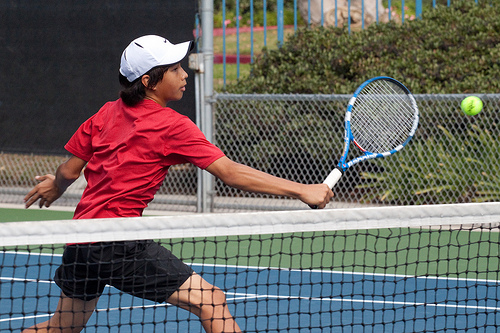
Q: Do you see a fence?
A: Yes, there is a fence.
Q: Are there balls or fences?
A: Yes, there is a fence.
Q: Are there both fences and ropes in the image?
A: No, there is a fence but no ropes.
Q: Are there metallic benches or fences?
A: Yes, there is a metal fence.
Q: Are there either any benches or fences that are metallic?
A: Yes, the fence is metallic.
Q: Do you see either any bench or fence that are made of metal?
A: Yes, the fence is made of metal.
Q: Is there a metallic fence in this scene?
A: Yes, there is a metal fence.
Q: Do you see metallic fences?
A: Yes, there is a metal fence.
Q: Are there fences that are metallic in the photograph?
A: Yes, there is a metal fence.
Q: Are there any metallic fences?
A: Yes, there is a metal fence.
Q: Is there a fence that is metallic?
A: Yes, there is a fence that is metallic.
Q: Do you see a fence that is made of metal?
A: Yes, there is a fence that is made of metal.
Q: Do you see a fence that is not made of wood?
A: Yes, there is a fence that is made of metal.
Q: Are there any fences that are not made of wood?
A: Yes, there is a fence that is made of metal.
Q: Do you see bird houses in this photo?
A: No, there are no bird houses.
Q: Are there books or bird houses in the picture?
A: No, there are no bird houses or books.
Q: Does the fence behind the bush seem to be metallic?
A: Yes, the fence is metallic.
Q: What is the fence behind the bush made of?
A: The fence is made of metal.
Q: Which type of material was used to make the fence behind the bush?
A: The fence is made of metal.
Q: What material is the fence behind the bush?
A: The fence is made of metal.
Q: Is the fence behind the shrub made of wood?
A: No, the fence is made of metal.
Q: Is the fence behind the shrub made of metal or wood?
A: The fence is made of metal.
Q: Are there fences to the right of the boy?
A: Yes, there is a fence to the right of the boy.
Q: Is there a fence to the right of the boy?
A: Yes, there is a fence to the right of the boy.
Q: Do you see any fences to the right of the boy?
A: Yes, there is a fence to the right of the boy.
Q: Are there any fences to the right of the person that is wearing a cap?
A: Yes, there is a fence to the right of the boy.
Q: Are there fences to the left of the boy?
A: No, the fence is to the right of the boy.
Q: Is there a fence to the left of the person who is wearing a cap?
A: No, the fence is to the right of the boy.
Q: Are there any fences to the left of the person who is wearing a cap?
A: No, the fence is to the right of the boy.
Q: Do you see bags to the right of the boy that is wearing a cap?
A: No, there is a fence to the right of the boy.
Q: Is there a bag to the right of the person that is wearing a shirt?
A: No, there is a fence to the right of the boy.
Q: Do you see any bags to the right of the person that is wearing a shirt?
A: No, there is a fence to the right of the boy.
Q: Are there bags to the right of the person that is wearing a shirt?
A: No, there is a fence to the right of the boy.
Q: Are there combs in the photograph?
A: No, there are no combs.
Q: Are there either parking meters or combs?
A: No, there are no combs or parking meters.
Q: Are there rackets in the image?
A: Yes, there is a racket.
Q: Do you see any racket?
A: Yes, there is a racket.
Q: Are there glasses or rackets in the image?
A: Yes, there is a racket.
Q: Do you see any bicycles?
A: No, there are no bicycles.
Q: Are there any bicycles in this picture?
A: No, there are no bicycles.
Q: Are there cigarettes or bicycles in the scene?
A: No, there are no bicycles or cigarettes.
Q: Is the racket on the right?
A: Yes, the racket is on the right of the image.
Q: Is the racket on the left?
A: No, the racket is on the right of the image.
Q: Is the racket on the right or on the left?
A: The racket is on the right of the image.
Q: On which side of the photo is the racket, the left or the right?
A: The racket is on the right of the image.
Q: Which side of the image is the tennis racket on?
A: The tennis racket is on the right of the image.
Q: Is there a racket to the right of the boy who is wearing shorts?
A: Yes, there is a racket to the right of the boy.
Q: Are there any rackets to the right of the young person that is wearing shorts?
A: Yes, there is a racket to the right of the boy.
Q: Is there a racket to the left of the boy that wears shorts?
A: No, the racket is to the right of the boy.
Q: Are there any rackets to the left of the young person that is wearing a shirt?
A: No, the racket is to the right of the boy.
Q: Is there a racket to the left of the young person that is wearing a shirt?
A: No, the racket is to the right of the boy.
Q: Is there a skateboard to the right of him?
A: No, there is a racket to the right of the boy.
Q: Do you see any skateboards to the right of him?
A: No, there is a racket to the right of the boy.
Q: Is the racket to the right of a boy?
A: Yes, the racket is to the right of a boy.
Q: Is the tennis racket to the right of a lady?
A: No, the tennis racket is to the right of a boy.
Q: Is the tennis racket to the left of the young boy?
A: No, the tennis racket is to the right of the boy.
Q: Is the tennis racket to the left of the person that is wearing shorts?
A: No, the tennis racket is to the right of the boy.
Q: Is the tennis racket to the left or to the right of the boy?
A: The tennis racket is to the right of the boy.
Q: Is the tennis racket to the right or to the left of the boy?
A: The tennis racket is to the right of the boy.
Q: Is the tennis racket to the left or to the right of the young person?
A: The tennis racket is to the right of the boy.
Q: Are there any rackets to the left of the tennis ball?
A: Yes, there is a racket to the left of the tennis ball.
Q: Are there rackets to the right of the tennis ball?
A: No, the racket is to the left of the tennis ball.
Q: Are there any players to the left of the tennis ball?
A: No, there is a racket to the left of the tennis ball.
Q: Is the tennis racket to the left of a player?
A: No, the tennis racket is to the left of the tennis ball.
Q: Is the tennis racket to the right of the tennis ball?
A: No, the tennis racket is to the left of the tennis ball.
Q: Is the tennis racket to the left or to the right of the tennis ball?
A: The tennis racket is to the left of the tennis ball.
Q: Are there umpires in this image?
A: No, there are no umpires.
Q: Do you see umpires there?
A: No, there are no umpires.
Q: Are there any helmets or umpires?
A: No, there are no umpires or helmets.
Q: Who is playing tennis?
A: The boy is playing tennis.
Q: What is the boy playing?
A: The boy is playing tennis.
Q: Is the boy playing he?
A: Yes, the boy is playing tennis.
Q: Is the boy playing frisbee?
A: No, the boy is playing tennis.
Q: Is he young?
A: Yes, the boy is young.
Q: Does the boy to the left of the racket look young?
A: Yes, the boy is young.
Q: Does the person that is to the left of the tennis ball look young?
A: Yes, the boy is young.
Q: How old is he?
A: The boy is young.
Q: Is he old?
A: No, the boy is young.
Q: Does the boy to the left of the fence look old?
A: No, the boy is young.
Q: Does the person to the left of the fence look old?
A: No, the boy is young.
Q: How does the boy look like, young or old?
A: The boy is young.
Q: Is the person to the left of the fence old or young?
A: The boy is young.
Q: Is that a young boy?
A: Yes, that is a young boy.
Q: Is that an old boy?
A: No, that is a young boy.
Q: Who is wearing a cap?
A: The boy is wearing a cap.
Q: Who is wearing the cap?
A: The boy is wearing a cap.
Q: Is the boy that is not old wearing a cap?
A: Yes, the boy is wearing a cap.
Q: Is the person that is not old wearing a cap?
A: Yes, the boy is wearing a cap.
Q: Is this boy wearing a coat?
A: No, the boy is wearing a cap.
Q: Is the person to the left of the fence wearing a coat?
A: No, the boy is wearing a cap.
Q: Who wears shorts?
A: The boy wears shorts.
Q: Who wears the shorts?
A: The boy wears shorts.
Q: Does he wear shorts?
A: Yes, the boy wears shorts.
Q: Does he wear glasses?
A: No, the boy wears shorts.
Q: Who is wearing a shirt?
A: The boy is wearing a shirt.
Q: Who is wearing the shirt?
A: The boy is wearing a shirt.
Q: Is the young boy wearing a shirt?
A: Yes, the boy is wearing a shirt.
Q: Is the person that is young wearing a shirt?
A: Yes, the boy is wearing a shirt.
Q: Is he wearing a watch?
A: No, the boy is wearing a shirt.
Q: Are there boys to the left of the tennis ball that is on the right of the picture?
A: Yes, there is a boy to the left of the tennis ball.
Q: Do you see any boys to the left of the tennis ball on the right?
A: Yes, there is a boy to the left of the tennis ball.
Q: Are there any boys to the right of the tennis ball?
A: No, the boy is to the left of the tennis ball.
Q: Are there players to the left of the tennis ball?
A: No, there is a boy to the left of the tennis ball.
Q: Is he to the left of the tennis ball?
A: Yes, the boy is to the left of the tennis ball.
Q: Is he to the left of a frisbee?
A: No, the boy is to the left of the tennis ball.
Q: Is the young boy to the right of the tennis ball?
A: No, the boy is to the left of the tennis ball.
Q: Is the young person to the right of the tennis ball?
A: No, the boy is to the left of the tennis ball.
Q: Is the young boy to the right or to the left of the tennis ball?
A: The boy is to the left of the tennis ball.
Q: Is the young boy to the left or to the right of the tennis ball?
A: The boy is to the left of the tennis ball.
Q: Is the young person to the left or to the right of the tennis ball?
A: The boy is to the left of the tennis ball.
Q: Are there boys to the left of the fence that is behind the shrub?
A: Yes, there is a boy to the left of the fence.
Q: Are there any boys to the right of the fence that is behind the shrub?
A: No, the boy is to the left of the fence.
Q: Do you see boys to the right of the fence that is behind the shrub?
A: No, the boy is to the left of the fence.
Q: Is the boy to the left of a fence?
A: Yes, the boy is to the left of a fence.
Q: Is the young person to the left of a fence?
A: Yes, the boy is to the left of a fence.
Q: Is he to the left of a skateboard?
A: No, the boy is to the left of a fence.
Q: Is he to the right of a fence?
A: No, the boy is to the left of a fence.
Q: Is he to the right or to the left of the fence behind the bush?
A: The boy is to the left of the fence.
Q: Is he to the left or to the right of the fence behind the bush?
A: The boy is to the left of the fence.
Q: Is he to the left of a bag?
A: No, the boy is to the left of the fence.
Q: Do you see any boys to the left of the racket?
A: Yes, there is a boy to the left of the racket.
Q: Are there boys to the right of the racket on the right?
A: No, the boy is to the left of the tennis racket.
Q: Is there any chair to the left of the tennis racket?
A: No, there is a boy to the left of the tennis racket.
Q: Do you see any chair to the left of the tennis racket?
A: No, there is a boy to the left of the tennis racket.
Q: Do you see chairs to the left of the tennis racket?
A: No, there is a boy to the left of the tennis racket.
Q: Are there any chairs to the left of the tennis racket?
A: No, there is a boy to the left of the tennis racket.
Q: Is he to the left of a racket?
A: Yes, the boy is to the left of a racket.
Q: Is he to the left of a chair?
A: No, the boy is to the left of a racket.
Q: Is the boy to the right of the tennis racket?
A: No, the boy is to the left of the tennis racket.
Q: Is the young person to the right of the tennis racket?
A: No, the boy is to the left of the tennis racket.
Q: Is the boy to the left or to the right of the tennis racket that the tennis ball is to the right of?
A: The boy is to the left of the tennis racket.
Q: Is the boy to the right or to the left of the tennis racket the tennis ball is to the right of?
A: The boy is to the left of the tennis racket.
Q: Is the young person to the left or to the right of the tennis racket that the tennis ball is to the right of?
A: The boy is to the left of the tennis racket.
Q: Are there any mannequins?
A: No, there are no mannequins.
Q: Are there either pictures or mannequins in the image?
A: No, there are no mannequins or pictures.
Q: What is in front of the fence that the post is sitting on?
A: The shrub is in front of the fence.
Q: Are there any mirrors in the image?
A: No, there are no mirrors.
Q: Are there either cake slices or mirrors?
A: No, there are no mirrors or cake slices.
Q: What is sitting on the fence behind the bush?
A: The post is sitting on the fence.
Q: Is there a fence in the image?
A: Yes, there is a fence.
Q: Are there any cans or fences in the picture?
A: Yes, there is a fence.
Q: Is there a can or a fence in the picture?
A: Yes, there is a fence.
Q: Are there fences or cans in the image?
A: Yes, there is a fence.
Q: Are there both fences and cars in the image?
A: No, there is a fence but no cars.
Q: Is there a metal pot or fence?
A: Yes, there is a metal fence.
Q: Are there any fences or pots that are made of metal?
A: Yes, the fence is made of metal.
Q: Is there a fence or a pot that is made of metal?
A: Yes, the fence is made of metal.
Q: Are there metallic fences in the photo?
A: Yes, there is a metal fence.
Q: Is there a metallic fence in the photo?
A: Yes, there is a metal fence.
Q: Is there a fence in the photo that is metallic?
A: Yes, there is a fence that is metallic.